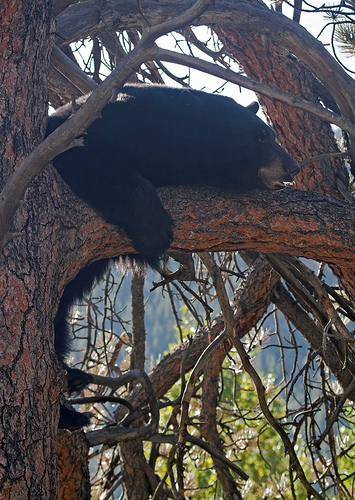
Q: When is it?
A: Daytime.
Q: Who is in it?
A: The bear.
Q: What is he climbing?
A: The tree.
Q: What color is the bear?
A: Black.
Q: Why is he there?
A: For food.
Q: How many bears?
A: 1.